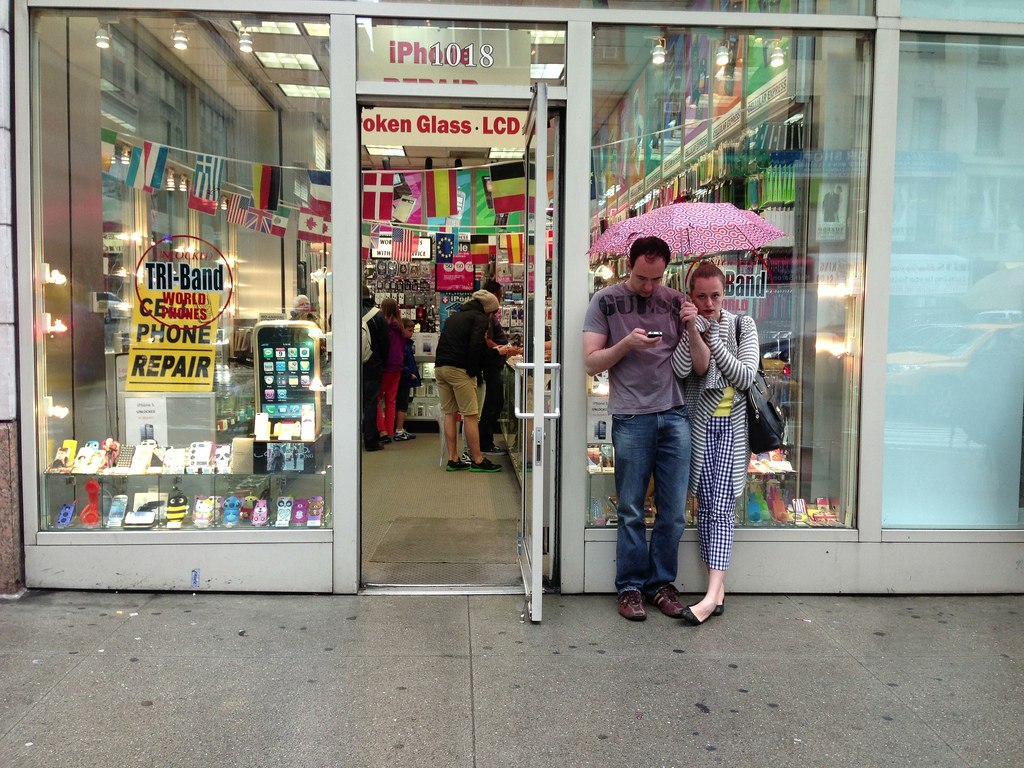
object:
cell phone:
[254, 321, 320, 437]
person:
[433, 289, 508, 472]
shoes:
[446, 457, 503, 473]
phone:
[646, 331, 662, 338]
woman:
[670, 259, 761, 625]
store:
[9, 0, 1021, 595]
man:
[582, 236, 712, 620]